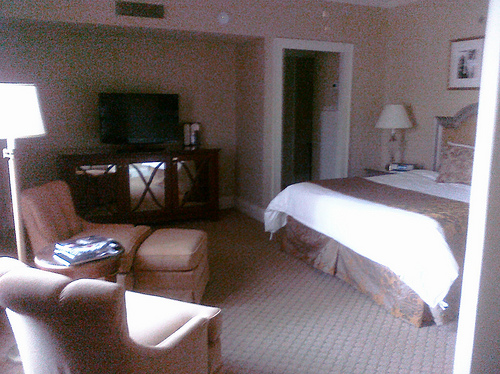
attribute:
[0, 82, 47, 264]
floor lamp — lit, tall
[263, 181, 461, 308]
blanket — folded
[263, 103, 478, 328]
bed — made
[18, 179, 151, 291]
chair — champaigne color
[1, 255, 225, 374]
chair — champaigne color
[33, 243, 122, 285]
end table — brown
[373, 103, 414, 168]
lamp — glass, white shaded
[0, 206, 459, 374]
floor — carpet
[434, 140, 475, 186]
pillow — brown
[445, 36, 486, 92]
picture — white matted, wood framed, framed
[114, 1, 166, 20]
vent — near ceiling, long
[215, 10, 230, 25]
fire alarm — white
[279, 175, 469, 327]
blanket — brown, long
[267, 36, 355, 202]
doorway — white framed, leading to bathroom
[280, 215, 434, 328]
bed skirt — brown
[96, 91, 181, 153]
television — flat screen, large, black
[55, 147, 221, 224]
stand — brown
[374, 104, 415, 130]
lamp shade — white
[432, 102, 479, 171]
headboard — brown, partially visible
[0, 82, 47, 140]
lamp shade — white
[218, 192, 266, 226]
floor trim — white